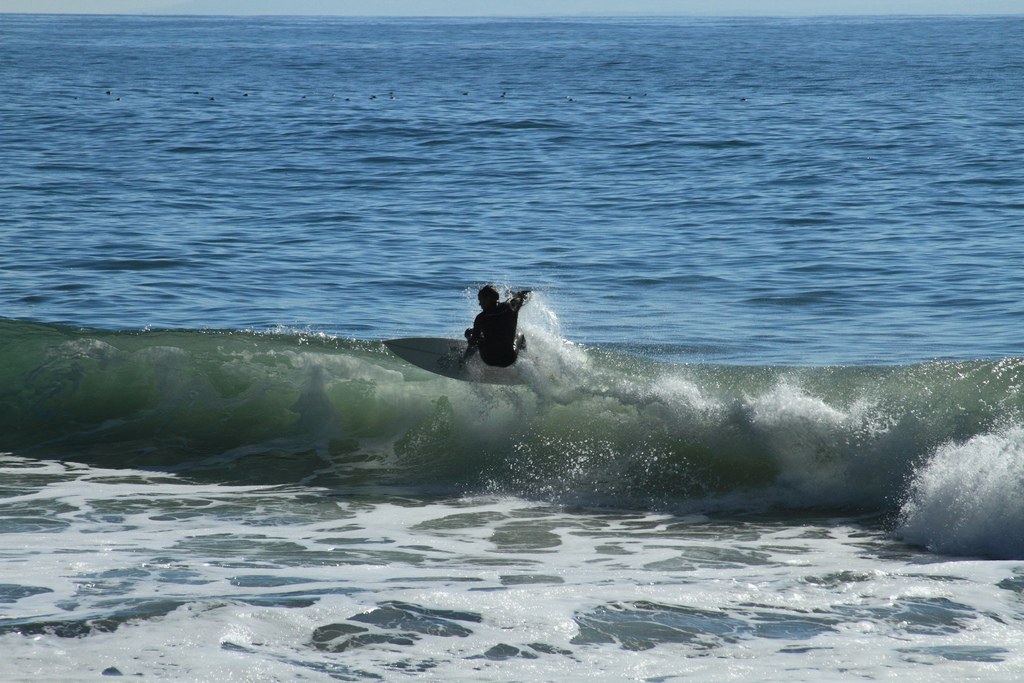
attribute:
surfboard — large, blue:
[367, 328, 542, 395]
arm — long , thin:
[452, 317, 485, 365]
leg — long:
[508, 324, 530, 361]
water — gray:
[572, 596, 739, 640]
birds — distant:
[300, 41, 836, 119]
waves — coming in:
[17, 105, 1003, 324]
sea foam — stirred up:
[9, 507, 1021, 678]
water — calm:
[9, 19, 1018, 354]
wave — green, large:
[6, 295, 1018, 548]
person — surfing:
[459, 281, 542, 368]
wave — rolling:
[649, 365, 1010, 541]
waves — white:
[79, 337, 1021, 552]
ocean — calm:
[7, 7, 1021, 228]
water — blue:
[143, 0, 977, 234]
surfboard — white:
[381, 329, 546, 390]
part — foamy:
[12, 465, 1021, 669]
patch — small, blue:
[644, 0, 873, 16]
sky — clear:
[1, 0, 1021, 18]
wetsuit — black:
[469, 303, 524, 362]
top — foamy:
[660, 381, 998, 446]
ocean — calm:
[595, 80, 879, 418]